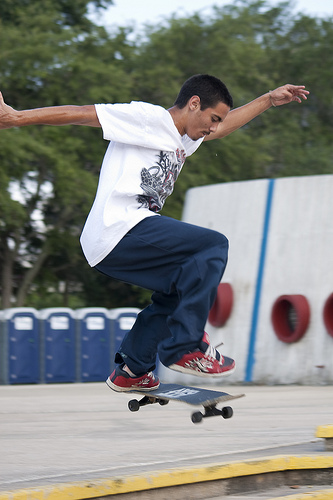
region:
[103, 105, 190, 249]
a beautiful white shirt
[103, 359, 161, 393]
shoe of a men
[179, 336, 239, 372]
right shoe of men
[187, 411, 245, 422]
front wheel of the machine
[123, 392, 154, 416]
back wheel of the machine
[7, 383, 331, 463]
a clean soft play ground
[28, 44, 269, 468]
a cool handsome guy on air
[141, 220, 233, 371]
two legs of a men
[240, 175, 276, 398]
a light blue poll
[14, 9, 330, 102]
a beautiful green trees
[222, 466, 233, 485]
the line is yellow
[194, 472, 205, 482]
the line is yellow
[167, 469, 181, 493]
the line is yellow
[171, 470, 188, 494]
the line is yellow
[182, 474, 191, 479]
the line is yellow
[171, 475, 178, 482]
the line is yellow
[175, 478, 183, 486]
the line is yellow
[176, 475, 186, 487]
the line is yellow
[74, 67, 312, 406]
man jumping with skateboard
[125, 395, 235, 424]
wheels on bottom of skateboard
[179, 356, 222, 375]
design on red sneakers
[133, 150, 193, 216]
design on white tee shirt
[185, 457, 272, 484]
yellow edge on cement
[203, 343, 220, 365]
white laces on shoe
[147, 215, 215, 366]
baggy blue pant leg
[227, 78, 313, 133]
extended arm of man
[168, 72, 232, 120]
short black hair on man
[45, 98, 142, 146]
short sleeve on arm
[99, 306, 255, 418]
red and black sneakers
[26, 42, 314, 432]
man doing a skateboarding trick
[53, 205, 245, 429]
baggy dark blue pants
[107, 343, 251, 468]
black skateboard with black wheels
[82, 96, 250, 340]
white t-shirt with graphics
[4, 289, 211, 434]
row of blue portipotties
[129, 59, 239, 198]
man with a thin black mustache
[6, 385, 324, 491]
large cement block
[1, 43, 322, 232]
man with his arms outstretched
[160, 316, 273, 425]
sneakers with white laces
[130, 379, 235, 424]
blue skateboard with white letters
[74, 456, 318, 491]
yellow stripe on curb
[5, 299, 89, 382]
blue and white out buildings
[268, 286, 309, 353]
red painted openings in concrete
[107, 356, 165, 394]
black,white and red sneaker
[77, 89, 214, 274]
white short sleeve tee shirt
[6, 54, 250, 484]
man doing a trick on skateboard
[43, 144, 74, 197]
green leaves on trees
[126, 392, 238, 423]
black wheels at bottom of skateboard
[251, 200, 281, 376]
dark blue stripe down wall